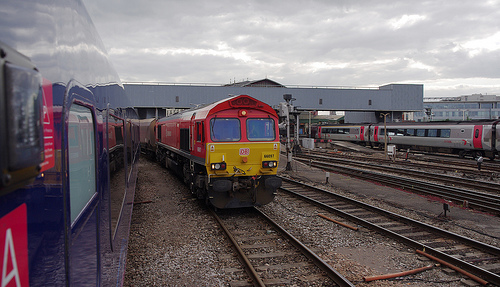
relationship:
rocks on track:
[296, 224, 315, 234] [224, 233, 319, 261]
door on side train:
[59, 75, 106, 285] [149, 90, 284, 213]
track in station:
[208, 205, 355, 286] [125, 79, 432, 124]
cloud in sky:
[113, 51, 252, 83] [84, 2, 499, 98]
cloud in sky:
[92, 3, 257, 47] [84, 2, 499, 98]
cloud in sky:
[274, 55, 435, 87] [84, 2, 499, 98]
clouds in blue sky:
[104, 0, 494, 83] [0, 0, 499, 97]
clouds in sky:
[78, 49, 133, 112] [124, 2, 499, 71]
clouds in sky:
[145, 7, 469, 79] [84, 49, 140, 119]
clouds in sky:
[75, 52, 147, 118] [243, 7, 405, 68]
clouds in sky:
[334, 11, 488, 69] [79, 49, 149, 76]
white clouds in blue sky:
[135, 20, 231, 77] [277, 28, 384, 103]